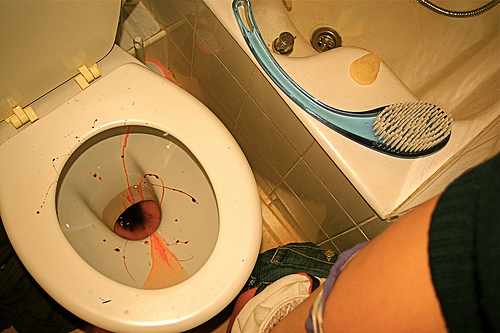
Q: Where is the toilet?
A: Next to the person.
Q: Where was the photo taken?
A: Bathroom.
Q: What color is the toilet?
A: White.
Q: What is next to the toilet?
A: Brush.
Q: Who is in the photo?
A: One person.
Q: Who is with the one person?
A: No one.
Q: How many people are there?
A: One.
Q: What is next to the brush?
A: Tub.